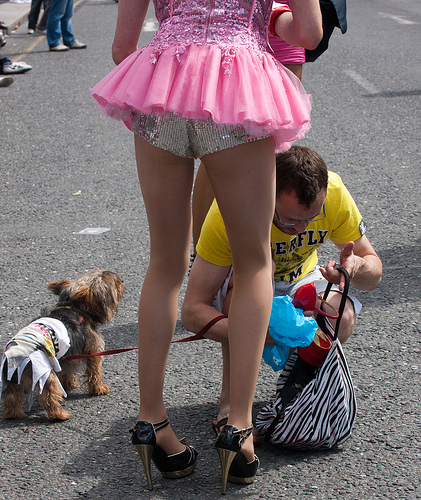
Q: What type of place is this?
A: It is a street.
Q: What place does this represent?
A: It represents the street.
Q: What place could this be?
A: It is a street.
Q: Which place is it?
A: It is a street.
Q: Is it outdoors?
A: Yes, it is outdoors.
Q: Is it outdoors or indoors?
A: It is outdoors.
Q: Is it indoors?
A: No, it is outdoors.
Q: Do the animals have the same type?
A: No, they are dogs and zebras.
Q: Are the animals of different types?
A: Yes, they are dogs and zebras.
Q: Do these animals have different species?
A: Yes, they are dogs and zebras.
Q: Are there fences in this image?
A: No, there are no fences.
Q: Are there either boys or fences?
A: No, there are no fences or boys.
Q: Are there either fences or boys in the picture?
A: No, there are no fences or boys.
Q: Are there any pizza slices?
A: No, there are no pizza slices.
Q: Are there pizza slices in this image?
A: No, there are no pizza slices.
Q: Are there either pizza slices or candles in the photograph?
A: No, there are no pizza slices or candles.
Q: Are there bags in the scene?
A: Yes, there is a bag.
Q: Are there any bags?
A: Yes, there is a bag.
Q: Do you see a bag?
A: Yes, there is a bag.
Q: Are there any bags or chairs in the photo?
A: Yes, there is a bag.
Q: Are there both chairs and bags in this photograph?
A: No, there is a bag but no chairs.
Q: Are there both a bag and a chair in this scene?
A: No, there is a bag but no chairs.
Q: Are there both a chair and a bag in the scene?
A: No, there is a bag but no chairs.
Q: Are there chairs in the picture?
A: No, there are no chairs.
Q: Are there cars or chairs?
A: No, there are no chairs or cars.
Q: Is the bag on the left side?
A: No, the bag is on the right of the image.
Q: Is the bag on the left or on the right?
A: The bag is on the right of the image.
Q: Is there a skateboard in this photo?
A: No, there are no skateboards.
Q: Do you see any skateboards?
A: No, there are no skateboards.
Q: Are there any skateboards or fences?
A: No, there are no skateboards or fences.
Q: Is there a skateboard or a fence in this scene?
A: No, there are no skateboards or fences.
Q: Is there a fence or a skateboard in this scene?
A: No, there are no skateboards or fences.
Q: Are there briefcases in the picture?
A: No, there are no briefcases.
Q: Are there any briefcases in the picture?
A: No, there are no briefcases.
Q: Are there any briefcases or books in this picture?
A: No, there are no briefcases or books.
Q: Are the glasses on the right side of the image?
A: Yes, the glasses are on the right of the image.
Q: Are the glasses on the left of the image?
A: No, the glasses are on the right of the image.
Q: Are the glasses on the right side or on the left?
A: The glasses are on the right of the image.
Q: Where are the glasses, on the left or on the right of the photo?
A: The glasses are on the right of the image.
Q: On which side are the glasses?
A: The glasses are on the right of the image.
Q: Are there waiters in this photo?
A: No, there are no waiters.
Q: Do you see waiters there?
A: No, there are no waiters.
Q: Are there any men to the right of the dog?
A: Yes, there is a man to the right of the dog.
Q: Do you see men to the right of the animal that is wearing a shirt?
A: Yes, there is a man to the right of the dog.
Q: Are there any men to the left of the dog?
A: No, the man is to the right of the dog.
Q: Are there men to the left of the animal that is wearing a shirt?
A: No, the man is to the right of the dog.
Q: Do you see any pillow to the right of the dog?
A: No, there is a man to the right of the dog.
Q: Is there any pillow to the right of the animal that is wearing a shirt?
A: No, there is a man to the right of the dog.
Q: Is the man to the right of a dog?
A: Yes, the man is to the right of a dog.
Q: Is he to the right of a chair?
A: No, the man is to the right of a dog.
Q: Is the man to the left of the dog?
A: No, the man is to the right of the dog.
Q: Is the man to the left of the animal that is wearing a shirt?
A: No, the man is to the right of the dog.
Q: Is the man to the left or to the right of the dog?
A: The man is to the right of the dog.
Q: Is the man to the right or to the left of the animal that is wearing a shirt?
A: The man is to the right of the dog.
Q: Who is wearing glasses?
A: The man is wearing glasses.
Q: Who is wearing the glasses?
A: The man is wearing glasses.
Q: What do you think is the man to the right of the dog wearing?
A: The man is wearing glasses.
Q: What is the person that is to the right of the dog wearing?
A: The man is wearing glasses.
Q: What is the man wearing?
A: The man is wearing glasses.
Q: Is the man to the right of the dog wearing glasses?
A: Yes, the man is wearing glasses.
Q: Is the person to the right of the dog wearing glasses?
A: Yes, the man is wearing glasses.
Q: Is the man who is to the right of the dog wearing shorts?
A: No, the man is wearing glasses.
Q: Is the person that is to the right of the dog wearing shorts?
A: No, the man is wearing glasses.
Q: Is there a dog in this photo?
A: Yes, there is a dog.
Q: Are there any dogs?
A: Yes, there is a dog.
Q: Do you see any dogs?
A: Yes, there is a dog.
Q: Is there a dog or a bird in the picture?
A: Yes, there is a dog.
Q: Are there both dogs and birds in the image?
A: No, there is a dog but no birds.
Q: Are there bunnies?
A: No, there are no bunnies.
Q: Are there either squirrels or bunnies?
A: No, there are no bunnies or squirrels.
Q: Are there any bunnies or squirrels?
A: No, there are no bunnies or squirrels.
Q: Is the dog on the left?
A: Yes, the dog is on the left of the image.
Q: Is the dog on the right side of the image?
A: No, the dog is on the left of the image.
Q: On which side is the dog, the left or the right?
A: The dog is on the left of the image.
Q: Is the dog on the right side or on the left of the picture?
A: The dog is on the left of the image.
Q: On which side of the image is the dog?
A: The dog is on the left of the image.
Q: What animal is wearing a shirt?
A: The dog is wearing a shirt.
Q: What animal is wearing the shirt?
A: The dog is wearing a shirt.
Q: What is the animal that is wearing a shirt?
A: The animal is a dog.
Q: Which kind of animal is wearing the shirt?
A: The animal is a dog.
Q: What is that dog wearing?
A: The dog is wearing a shirt.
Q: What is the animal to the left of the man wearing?
A: The dog is wearing a shirt.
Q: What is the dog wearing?
A: The dog is wearing a shirt.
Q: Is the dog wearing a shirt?
A: Yes, the dog is wearing a shirt.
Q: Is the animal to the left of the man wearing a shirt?
A: Yes, the dog is wearing a shirt.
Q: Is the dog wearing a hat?
A: No, the dog is wearing a shirt.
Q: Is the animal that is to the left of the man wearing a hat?
A: No, the dog is wearing a shirt.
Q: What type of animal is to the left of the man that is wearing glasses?
A: The animal is a dog.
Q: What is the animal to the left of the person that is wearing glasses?
A: The animal is a dog.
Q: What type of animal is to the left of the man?
A: The animal is a dog.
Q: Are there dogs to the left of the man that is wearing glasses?
A: Yes, there is a dog to the left of the man.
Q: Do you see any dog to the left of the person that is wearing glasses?
A: Yes, there is a dog to the left of the man.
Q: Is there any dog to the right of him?
A: No, the dog is to the left of the man.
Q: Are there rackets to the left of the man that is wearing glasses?
A: No, there is a dog to the left of the man.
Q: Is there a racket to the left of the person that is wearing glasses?
A: No, there is a dog to the left of the man.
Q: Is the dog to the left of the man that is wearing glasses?
A: Yes, the dog is to the left of the man.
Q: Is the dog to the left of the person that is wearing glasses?
A: Yes, the dog is to the left of the man.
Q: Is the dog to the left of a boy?
A: No, the dog is to the left of the man.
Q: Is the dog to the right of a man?
A: No, the dog is to the left of a man.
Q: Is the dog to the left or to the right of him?
A: The dog is to the left of the man.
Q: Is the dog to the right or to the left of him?
A: The dog is to the left of the man.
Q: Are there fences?
A: No, there are no fences.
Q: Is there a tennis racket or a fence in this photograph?
A: No, there are no fences or rackets.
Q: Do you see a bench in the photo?
A: No, there are no benches.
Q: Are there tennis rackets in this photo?
A: No, there are no tennis rackets.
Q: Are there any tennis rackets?
A: No, there are no tennis rackets.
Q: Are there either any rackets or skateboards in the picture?
A: No, there are no rackets or skateboards.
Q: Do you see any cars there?
A: No, there are no cars.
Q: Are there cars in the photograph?
A: No, there are no cars.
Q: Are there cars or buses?
A: No, there are no cars or buses.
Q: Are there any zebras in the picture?
A: Yes, there is a zebra.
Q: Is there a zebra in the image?
A: Yes, there is a zebra.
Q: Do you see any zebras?
A: Yes, there is a zebra.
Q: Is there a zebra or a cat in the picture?
A: Yes, there is a zebra.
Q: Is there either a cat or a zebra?
A: Yes, there is a zebra.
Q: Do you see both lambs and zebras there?
A: No, there is a zebra but no lambs.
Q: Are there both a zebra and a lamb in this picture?
A: No, there is a zebra but no lambs.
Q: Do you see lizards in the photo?
A: No, there are no lizards.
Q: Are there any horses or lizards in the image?
A: No, there are no lizards or horses.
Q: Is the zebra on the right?
A: Yes, the zebra is on the right of the image.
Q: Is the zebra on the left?
A: No, the zebra is on the right of the image.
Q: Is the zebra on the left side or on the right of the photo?
A: The zebra is on the right of the image.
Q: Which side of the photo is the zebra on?
A: The zebra is on the right of the image.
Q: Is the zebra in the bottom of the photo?
A: Yes, the zebra is in the bottom of the image.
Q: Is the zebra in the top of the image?
A: No, the zebra is in the bottom of the image.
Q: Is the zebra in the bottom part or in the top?
A: The zebra is in the bottom of the image.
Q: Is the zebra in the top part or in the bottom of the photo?
A: The zebra is in the bottom of the image.